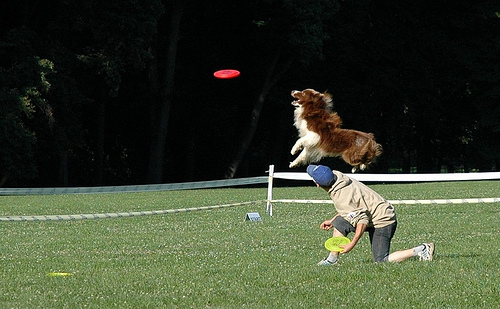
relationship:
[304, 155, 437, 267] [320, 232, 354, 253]
boy holding frisbee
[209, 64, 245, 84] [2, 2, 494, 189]
frisbee in air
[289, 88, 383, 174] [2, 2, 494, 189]
dog jumping in air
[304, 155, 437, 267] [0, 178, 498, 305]
boy in grass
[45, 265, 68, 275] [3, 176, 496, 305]
frisbee on ground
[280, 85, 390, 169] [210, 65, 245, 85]
dog trying to catch frisbee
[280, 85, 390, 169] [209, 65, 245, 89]
dog trying to catch frisbee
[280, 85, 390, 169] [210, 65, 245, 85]
dog catching frisbee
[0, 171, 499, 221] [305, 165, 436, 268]
fence behind boy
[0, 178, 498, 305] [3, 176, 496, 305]
grass on ground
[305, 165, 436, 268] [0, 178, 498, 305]
boy kneeling on grass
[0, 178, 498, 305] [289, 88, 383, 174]
grass under dog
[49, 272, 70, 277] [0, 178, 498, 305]
frisbee on grass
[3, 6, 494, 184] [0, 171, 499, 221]
tree behind fence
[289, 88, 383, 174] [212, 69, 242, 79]
dog jumping for frisbee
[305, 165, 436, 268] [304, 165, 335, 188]
boy in baseball cap